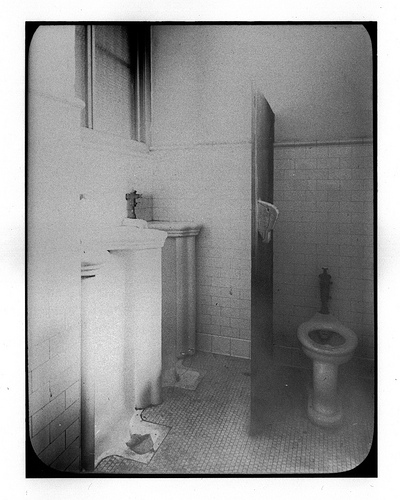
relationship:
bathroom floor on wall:
[94, 350, 373, 479] [251, 86, 276, 371]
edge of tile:
[290, 139, 371, 146] [279, 148, 373, 264]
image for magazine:
[27, 22, 374, 476] [33, 25, 373, 476]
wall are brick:
[146, 23, 373, 364] [315, 242, 339, 254]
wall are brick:
[146, 23, 373, 364] [340, 201, 362, 209]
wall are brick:
[146, 23, 373, 364] [318, 155, 339, 168]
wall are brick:
[146, 23, 373, 364] [271, 158, 294, 168]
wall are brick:
[146, 23, 373, 364] [303, 189, 326, 199]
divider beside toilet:
[232, 69, 292, 457] [294, 309, 359, 431]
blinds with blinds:
[85, 25, 150, 144] [74, 20, 140, 143]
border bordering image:
[27, 22, 379, 477] [27, 22, 374, 476]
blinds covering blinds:
[85, 29, 150, 147] [85, 25, 150, 144]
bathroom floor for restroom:
[94, 350, 373, 479] [32, 23, 376, 475]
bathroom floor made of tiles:
[94, 350, 373, 479] [186, 395, 301, 456]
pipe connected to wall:
[319, 266, 332, 314] [146, 23, 373, 364]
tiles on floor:
[112, 350, 379, 470] [172, 408, 281, 470]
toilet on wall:
[294, 267, 359, 427] [26, 20, 372, 474]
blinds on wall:
[85, 25, 150, 144] [19, 23, 185, 489]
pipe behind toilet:
[319, 267, 333, 314] [296, 313, 357, 425]